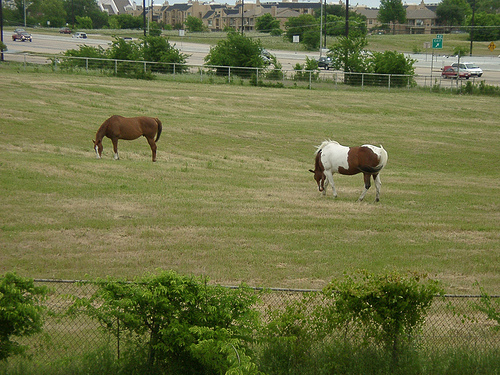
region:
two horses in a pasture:
[16, 69, 414, 242]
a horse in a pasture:
[303, 123, 396, 213]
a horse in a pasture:
[73, 98, 172, 163]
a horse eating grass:
[290, 115, 407, 219]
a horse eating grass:
[81, 98, 188, 170]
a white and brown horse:
[303, 127, 406, 204]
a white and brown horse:
[76, 100, 175, 186]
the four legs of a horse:
[108, 138, 161, 174]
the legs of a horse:
[110, 137, 158, 159]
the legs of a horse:
[322, 170, 385, 205]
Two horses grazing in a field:
[72, 95, 429, 243]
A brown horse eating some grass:
[85, 103, 179, 171]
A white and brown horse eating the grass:
[300, 132, 412, 220]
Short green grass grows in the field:
[116, 177, 286, 242]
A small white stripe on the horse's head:
[90, 142, 102, 162]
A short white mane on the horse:
[312, 135, 340, 156]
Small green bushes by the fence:
[108, 274, 249, 371]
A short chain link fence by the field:
[0, 273, 485, 362]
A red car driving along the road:
[10, 23, 36, 43]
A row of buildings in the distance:
[120, 2, 447, 40]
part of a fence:
[376, 141, 402, 312]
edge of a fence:
[268, 300, 278, 318]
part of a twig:
[338, 206, 363, 316]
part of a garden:
[231, 175, 241, 202]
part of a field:
[231, 163, 261, 225]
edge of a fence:
[286, 308, 306, 350]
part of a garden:
[318, 296, 330, 336]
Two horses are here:
[78, 100, 461, 231]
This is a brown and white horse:
[281, 121, 423, 221]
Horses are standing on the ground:
[66, 93, 440, 228]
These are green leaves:
[76, 253, 453, 360]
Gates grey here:
[10, 262, 496, 374]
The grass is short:
[128, 196, 354, 255]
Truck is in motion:
[8, 19, 46, 51]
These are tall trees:
[64, 24, 424, 93]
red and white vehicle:
[436, 58, 491, 82]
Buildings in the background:
[98, 3, 475, 47]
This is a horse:
[294, 118, 401, 203]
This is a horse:
[75, 105, 173, 165]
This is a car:
[434, 53, 489, 90]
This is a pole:
[357, 69, 368, 91]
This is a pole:
[385, 73, 395, 88]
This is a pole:
[404, 71, 414, 93]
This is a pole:
[455, 73, 465, 93]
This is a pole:
[332, 69, 342, 90]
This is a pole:
[305, 63, 317, 95]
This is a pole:
[251, 61, 263, 89]